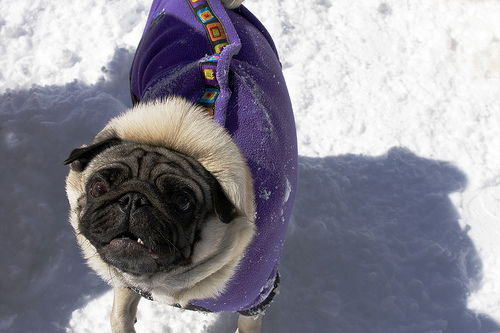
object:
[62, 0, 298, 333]
pug dog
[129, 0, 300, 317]
vest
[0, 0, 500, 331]
snow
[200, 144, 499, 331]
shadow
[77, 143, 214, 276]
face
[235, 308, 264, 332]
front leg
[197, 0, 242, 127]
closure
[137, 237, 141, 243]
tooth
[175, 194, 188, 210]
eye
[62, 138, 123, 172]
right ear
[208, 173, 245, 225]
left ear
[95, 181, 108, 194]
right eye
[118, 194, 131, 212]
right nostril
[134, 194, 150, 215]
left nostril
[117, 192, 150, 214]
nose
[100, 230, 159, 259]
mouth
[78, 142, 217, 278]
head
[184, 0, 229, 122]
stripe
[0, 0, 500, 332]
ground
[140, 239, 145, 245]
tooth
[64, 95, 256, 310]
fur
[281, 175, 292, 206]
snow